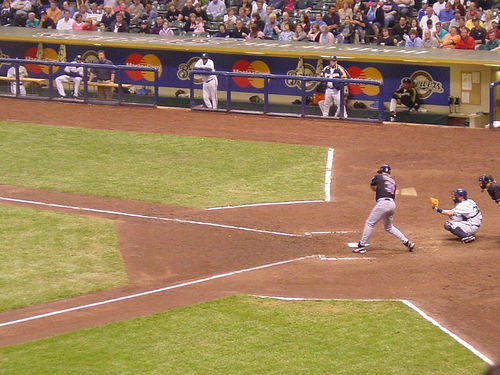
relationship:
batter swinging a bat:
[363, 161, 409, 247] [398, 187, 418, 197]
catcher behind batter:
[430, 186, 483, 243] [363, 160, 414, 250]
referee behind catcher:
[472, 181, 484, 190] [427, 182, 480, 238]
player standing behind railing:
[321, 58, 345, 118] [258, 75, 381, 119]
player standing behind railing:
[320, 58, 350, 121] [225, 67, 294, 108]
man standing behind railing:
[90, 54, 117, 94] [114, 61, 162, 100]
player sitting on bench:
[396, 80, 416, 111] [429, 99, 448, 119]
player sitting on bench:
[386, 73, 418, 118] [424, 104, 459, 115]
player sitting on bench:
[49, 49, 88, 96] [49, 79, 130, 97]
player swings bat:
[350, 163, 415, 253] [392, 187, 421, 202]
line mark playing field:
[2, 195, 300, 236] [2, 97, 482, 373]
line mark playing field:
[1, 254, 319, 327] [2, 97, 482, 373]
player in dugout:
[383, 76, 422, 125] [0, 38, 484, 128]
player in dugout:
[312, 54, 351, 119] [0, 38, 484, 128]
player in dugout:
[190, 52, 220, 111] [0, 38, 484, 128]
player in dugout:
[50, 55, 87, 102] [0, 38, 484, 128]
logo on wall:
[122, 49, 164, 81] [2, 45, 456, 105]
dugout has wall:
[0, 38, 484, 128] [2, 45, 456, 105]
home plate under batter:
[342, 239, 373, 248] [351, 159, 420, 257]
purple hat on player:
[448, 185, 469, 200] [440, 213, 470, 293]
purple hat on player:
[326, 121, 338, 136] [316, 50, 344, 103]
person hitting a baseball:
[332, 155, 422, 286] [336, 146, 412, 267]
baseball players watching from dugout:
[18, 79, 434, 109] [12, 99, 494, 172]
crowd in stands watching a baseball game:
[10, 51, 490, 147] [32, 141, 493, 375]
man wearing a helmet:
[424, 177, 485, 281] [452, 186, 468, 199]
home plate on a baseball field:
[328, 231, 374, 275] [2, 174, 487, 375]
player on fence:
[192, 53, 220, 109] [0, 54, 385, 123]